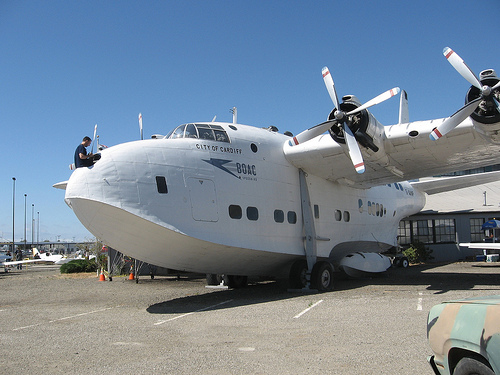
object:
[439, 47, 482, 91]
propeller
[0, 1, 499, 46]
sky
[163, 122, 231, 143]
cockpit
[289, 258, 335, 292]
wheels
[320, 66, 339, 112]
blade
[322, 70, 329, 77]
red stripe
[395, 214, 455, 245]
windows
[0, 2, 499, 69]
sky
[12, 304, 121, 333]
markings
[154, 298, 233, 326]
markings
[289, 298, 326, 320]
markings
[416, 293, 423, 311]
markings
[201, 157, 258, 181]
label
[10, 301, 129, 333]
white line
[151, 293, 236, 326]
white line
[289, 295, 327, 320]
white line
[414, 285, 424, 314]
white line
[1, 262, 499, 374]
pavement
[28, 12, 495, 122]
sky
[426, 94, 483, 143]
propeller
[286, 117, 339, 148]
propeller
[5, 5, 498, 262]
sky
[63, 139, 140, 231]
nose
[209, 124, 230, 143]
window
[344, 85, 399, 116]
propeller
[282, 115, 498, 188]
wing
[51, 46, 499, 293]
airplane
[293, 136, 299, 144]
line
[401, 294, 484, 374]
vehicle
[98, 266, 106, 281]
traffic cone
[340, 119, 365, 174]
propeller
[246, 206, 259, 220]
window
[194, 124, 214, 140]
window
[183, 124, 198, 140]
window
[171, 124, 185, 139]
window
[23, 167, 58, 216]
clouds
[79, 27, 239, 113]
sky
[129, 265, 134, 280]
traffic cone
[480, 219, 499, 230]
umbrella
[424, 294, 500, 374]
truck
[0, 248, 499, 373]
parking lot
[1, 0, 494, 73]
sky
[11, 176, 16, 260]
street lights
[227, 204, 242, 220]
window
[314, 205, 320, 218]
window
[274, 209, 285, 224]
window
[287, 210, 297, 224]
window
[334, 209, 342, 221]
window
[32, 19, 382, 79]
sky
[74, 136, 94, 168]
man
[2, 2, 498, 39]
clouds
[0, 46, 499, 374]
airport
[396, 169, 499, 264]
building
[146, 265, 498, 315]
shadow